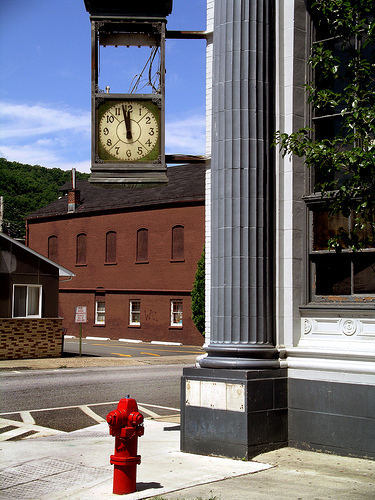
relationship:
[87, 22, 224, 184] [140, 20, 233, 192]
clock is mounted side of building mounted from side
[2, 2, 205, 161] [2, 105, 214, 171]
blue sky white clouds sky with white cloud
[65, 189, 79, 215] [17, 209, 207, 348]
chimney of building building building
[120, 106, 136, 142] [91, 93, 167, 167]
black hands hands of a clock clock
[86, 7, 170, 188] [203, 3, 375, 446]
clock hanging building building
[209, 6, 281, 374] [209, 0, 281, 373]
doric column building doric column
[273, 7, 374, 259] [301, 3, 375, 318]
tree branches front of window window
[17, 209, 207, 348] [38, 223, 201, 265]
brick building sealed off windows windows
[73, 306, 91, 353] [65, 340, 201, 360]
parking sign sign on a street street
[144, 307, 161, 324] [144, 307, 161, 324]
black graffit on wal a wall black graffit on wal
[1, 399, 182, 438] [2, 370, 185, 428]
white paint paint on street street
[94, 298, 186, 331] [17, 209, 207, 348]
three windows side of building building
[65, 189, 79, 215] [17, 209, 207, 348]
chimney on building top of building building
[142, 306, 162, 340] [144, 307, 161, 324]
black graffit on wal red brick wall black graffit on wal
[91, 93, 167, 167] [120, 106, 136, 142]
clock with face clock with hands two black hands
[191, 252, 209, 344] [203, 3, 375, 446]
tree on side side of building building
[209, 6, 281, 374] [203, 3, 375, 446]
gray pillar pillar on building building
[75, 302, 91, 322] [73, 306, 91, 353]
white sign in lot parking lot sign in parking lot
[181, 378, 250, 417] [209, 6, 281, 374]
section of base base of pillar pillar